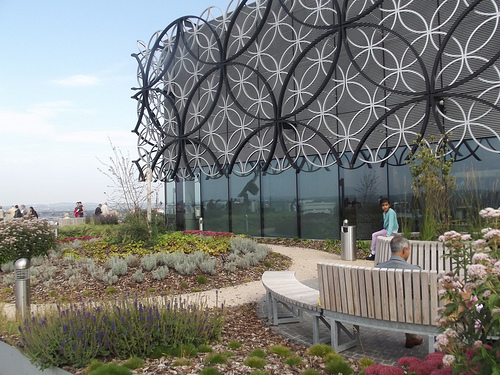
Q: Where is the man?
A: At the bench.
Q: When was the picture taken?
A: Daytime.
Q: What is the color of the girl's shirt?
A: Green.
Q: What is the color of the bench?
A: White.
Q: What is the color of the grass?
A: Green and yellow.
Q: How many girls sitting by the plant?
A: One.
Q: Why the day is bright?
A: It's sunny.